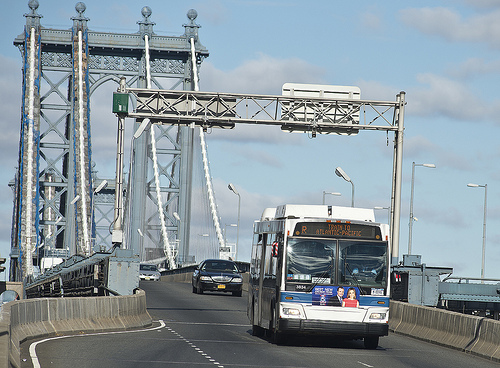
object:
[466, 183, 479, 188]
light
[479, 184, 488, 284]
pole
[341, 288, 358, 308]
woman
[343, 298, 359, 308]
top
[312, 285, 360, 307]
bus advertising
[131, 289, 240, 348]
street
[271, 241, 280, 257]
mirror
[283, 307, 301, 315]
headlight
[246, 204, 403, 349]
bus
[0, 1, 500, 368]
bridge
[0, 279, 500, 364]
road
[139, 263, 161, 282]
cars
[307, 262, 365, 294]
wiper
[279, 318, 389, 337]
black bumper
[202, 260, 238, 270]
windshield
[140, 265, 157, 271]
windshield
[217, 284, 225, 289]
license plate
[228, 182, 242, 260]
pillars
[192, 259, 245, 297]
car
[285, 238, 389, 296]
front